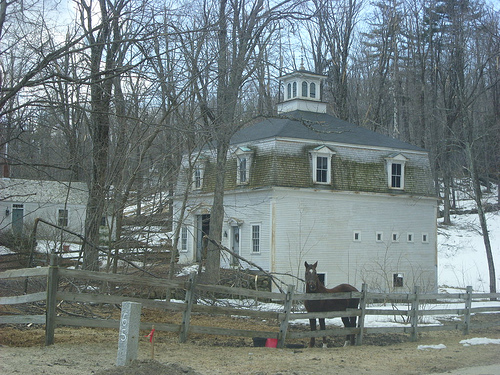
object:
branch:
[236, 1, 263, 89]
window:
[383, 151, 406, 190]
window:
[233, 144, 251, 186]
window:
[248, 220, 261, 256]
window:
[186, 160, 204, 191]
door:
[229, 222, 240, 267]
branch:
[250, 0, 331, 27]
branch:
[29, 31, 217, 86]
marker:
[122, 303, 134, 315]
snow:
[0, 174, 498, 351]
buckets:
[263, 335, 278, 348]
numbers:
[117, 327, 131, 343]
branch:
[0, 23, 104, 107]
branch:
[82, 0, 96, 45]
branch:
[15, 27, 90, 97]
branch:
[112, 18, 218, 58]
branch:
[151, 22, 168, 75]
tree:
[62, 2, 125, 273]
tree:
[183, 0, 356, 284]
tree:
[404, 0, 472, 223]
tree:
[302, 1, 363, 117]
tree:
[410, 0, 497, 302]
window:
[309, 151, 334, 186]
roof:
[180, 45, 439, 152]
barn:
[0, 181, 500, 373]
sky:
[0, 0, 499, 95]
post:
[148, 323, 153, 362]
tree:
[3, 1, 244, 275]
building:
[169, 50, 441, 306]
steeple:
[272, 43, 330, 115]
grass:
[0, 302, 282, 344]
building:
[0, 176, 89, 241]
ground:
[0, 299, 499, 374]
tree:
[173, 0, 272, 295]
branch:
[80, 142, 112, 270]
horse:
[299, 261, 363, 350]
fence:
[0, 250, 498, 349]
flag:
[141, 323, 157, 360]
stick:
[249, 272, 264, 315]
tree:
[141, 0, 328, 306]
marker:
[144, 323, 161, 343]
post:
[115, 300, 141, 369]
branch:
[87, 1, 119, 115]